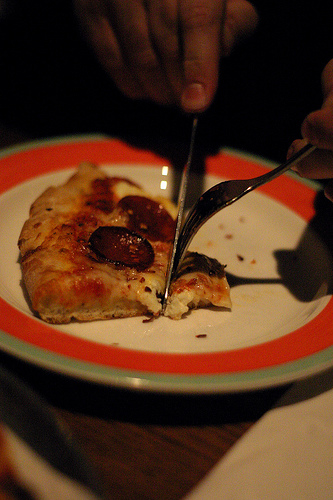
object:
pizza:
[18, 160, 232, 324]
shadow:
[1, 351, 332, 424]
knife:
[160, 116, 198, 301]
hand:
[86, 0, 260, 115]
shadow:
[271, 188, 332, 302]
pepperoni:
[85, 226, 153, 271]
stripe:
[0, 139, 332, 373]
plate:
[1, 133, 332, 394]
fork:
[170, 141, 314, 278]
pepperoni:
[113, 194, 177, 243]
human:
[86, 0, 333, 199]